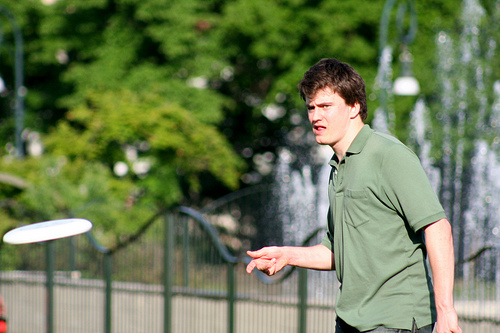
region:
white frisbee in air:
[0, 214, 97, 255]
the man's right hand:
[246, 238, 288, 280]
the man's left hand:
[428, 306, 462, 331]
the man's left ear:
[345, 94, 363, 121]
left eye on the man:
[322, 100, 329, 110]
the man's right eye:
[304, 102, 317, 112]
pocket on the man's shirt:
[334, 187, 375, 231]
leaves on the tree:
[105, 67, 226, 171]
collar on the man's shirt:
[350, 117, 373, 162]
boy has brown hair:
[295, 55, 353, 114]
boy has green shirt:
[317, 121, 392, 323]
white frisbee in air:
[1, 185, 83, 251]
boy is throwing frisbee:
[0, 199, 323, 286]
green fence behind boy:
[72, 193, 346, 332]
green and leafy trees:
[25, 10, 345, 220]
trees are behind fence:
[12, 20, 336, 227]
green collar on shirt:
[322, 107, 364, 194]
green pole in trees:
[0, 31, 42, 156]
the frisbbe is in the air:
[0, 212, 105, 264]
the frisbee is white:
[7, 221, 100, 248]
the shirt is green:
[324, 156, 433, 321]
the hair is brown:
[303, 54, 365, 94]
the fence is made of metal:
[131, 212, 228, 323]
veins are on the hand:
[430, 275, 446, 321]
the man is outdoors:
[230, 68, 462, 329]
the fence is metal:
[118, 217, 236, 329]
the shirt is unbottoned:
[320, 150, 365, 185]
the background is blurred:
[74, 26, 231, 181]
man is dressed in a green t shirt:
[271, 59, 436, 275]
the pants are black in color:
[332, 314, 424, 332]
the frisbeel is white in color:
[5, 215, 102, 247]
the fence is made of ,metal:
[161, 224, 218, 309]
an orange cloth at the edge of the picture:
[0, 288, 34, 331]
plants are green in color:
[363, 25, 472, 105]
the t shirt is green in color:
[340, 186, 395, 306]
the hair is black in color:
[313, 49, 374, 100]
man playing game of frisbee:
[245, 57, 465, 332]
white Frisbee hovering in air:
[2, 218, 92, 243]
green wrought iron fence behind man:
[1, 203, 498, 331]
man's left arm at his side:
[380, 142, 464, 332]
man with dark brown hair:
[245, 58, 464, 331]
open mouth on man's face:
[312, 123, 326, 133]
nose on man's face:
[312, 108, 320, 121]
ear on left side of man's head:
[350, 100, 362, 117]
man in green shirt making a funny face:
[240, 53, 465, 331]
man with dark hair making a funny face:
[242, 56, 466, 331]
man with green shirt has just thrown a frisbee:
[241, 55, 466, 331]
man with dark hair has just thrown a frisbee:
[243, 56, 462, 331]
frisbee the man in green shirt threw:
[0, 212, 94, 247]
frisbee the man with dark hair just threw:
[1, 214, 92, 248]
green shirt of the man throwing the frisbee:
[320, 122, 447, 329]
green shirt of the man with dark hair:
[305, 121, 447, 331]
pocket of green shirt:
[338, 186, 372, 228]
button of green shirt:
[331, 169, 338, 176]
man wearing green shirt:
[231, 50, 476, 332]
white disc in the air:
[0, 207, 105, 258]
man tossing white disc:
[1, 31, 473, 329]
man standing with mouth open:
[220, 36, 480, 331]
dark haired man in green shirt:
[224, 44, 478, 331]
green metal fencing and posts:
[110, 199, 225, 329]